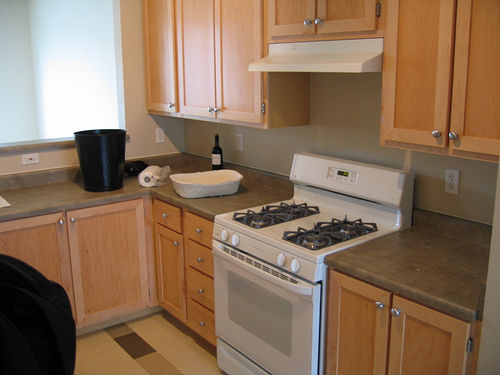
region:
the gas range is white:
[215, 120, 312, 344]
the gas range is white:
[254, 188, 351, 368]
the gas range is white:
[294, 237, 348, 374]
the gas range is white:
[215, 234, 279, 371]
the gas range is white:
[250, 192, 292, 353]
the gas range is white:
[251, 224, 322, 352]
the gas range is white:
[267, 141, 322, 371]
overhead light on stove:
[246, 27, 425, 92]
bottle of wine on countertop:
[201, 128, 226, 185]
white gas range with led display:
[237, 138, 404, 357]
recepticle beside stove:
[429, 153, 469, 215]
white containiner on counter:
[166, 163, 248, 206]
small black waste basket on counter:
[66, 129, 129, 199]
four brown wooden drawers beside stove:
[178, 203, 213, 350]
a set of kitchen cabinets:
[139, 9, 480, 116]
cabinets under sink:
[2, 188, 149, 339]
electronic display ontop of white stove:
[321, 160, 375, 195]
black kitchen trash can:
[72, 126, 139, 192]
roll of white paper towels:
[135, 160, 170, 186]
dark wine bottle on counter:
[203, 129, 229, 168]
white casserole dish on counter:
[167, 165, 248, 206]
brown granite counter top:
[367, 241, 484, 301]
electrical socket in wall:
[438, 166, 470, 199]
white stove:
[214, 144, 346, 374]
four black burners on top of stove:
[231, 193, 383, 245]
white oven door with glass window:
[201, 259, 319, 374]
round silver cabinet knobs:
[358, 297, 420, 332]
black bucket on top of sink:
[67, 127, 137, 195]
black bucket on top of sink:
[71, 125, 136, 184]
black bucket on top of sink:
[71, 119, 130, 195]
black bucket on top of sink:
[72, 124, 136, 192]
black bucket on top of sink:
[66, 121, 133, 196]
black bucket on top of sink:
[65, 127, 136, 199]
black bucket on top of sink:
[72, 121, 127, 199]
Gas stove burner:
[235, 208, 277, 230]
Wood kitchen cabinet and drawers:
[146, 197, 216, 343]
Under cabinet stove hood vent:
[254, 40, 384, 77]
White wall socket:
[442, 167, 460, 194]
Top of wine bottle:
[210, 129, 224, 159]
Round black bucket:
[76, 127, 129, 194]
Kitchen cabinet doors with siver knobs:
[142, 0, 264, 122]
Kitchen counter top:
[388, 231, 488, 303]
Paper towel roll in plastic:
[138, 163, 168, 193]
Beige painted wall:
[311, 78, 376, 153]